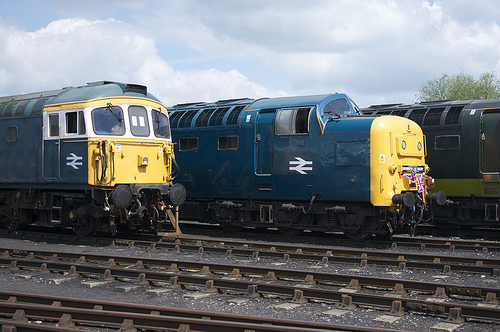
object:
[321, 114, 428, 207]
engines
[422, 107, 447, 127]
windows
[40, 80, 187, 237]
train front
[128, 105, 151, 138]
windows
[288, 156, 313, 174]
logo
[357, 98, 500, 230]
trains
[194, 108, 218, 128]
windows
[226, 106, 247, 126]
windows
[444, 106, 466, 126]
windows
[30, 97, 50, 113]
windows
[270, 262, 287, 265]
rocks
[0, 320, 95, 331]
track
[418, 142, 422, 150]
lights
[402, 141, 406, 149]
lights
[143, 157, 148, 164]
lights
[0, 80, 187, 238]
train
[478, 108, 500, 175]
door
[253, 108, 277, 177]
door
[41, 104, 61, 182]
door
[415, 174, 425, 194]
flag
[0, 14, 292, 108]
cloud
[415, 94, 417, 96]
leaves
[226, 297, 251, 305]
rocks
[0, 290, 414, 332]
tracks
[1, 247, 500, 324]
tracks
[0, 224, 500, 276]
tracks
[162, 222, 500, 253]
tracks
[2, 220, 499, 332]
ground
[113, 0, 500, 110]
clouds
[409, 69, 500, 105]
tree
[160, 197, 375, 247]
bottom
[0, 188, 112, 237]
bottom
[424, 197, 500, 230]
bottom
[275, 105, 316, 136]
window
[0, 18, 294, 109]
cloud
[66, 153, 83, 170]
logo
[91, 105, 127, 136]
window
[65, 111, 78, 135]
window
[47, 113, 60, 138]
window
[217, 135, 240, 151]
window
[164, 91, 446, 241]
train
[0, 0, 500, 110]
sky